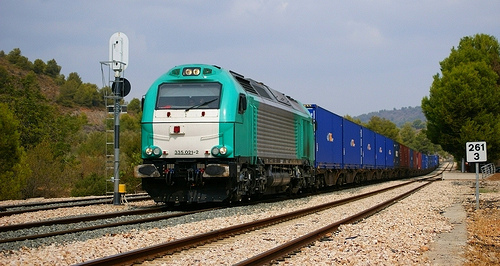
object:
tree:
[420, 33, 499, 173]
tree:
[6, 88, 55, 152]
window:
[249, 80, 276, 102]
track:
[0, 193, 152, 216]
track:
[1, 203, 218, 241]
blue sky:
[265, 20, 383, 89]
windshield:
[157, 81, 223, 109]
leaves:
[43, 117, 68, 142]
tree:
[13, 136, 63, 200]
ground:
[261, 111, 283, 156]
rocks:
[384, 242, 404, 254]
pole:
[475, 162, 480, 210]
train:
[131, 62, 439, 208]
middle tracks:
[0, 200, 247, 245]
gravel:
[0, 179, 457, 263]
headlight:
[153, 148, 161, 155]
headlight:
[219, 147, 227, 155]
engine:
[133, 63, 315, 210]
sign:
[465, 141, 487, 163]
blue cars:
[312, 104, 342, 170]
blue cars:
[343, 119, 362, 169]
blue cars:
[362, 126, 377, 168]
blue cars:
[375, 132, 386, 169]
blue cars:
[385, 136, 394, 168]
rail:
[71, 160, 455, 266]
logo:
[326, 132, 335, 143]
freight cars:
[309, 104, 439, 171]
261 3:
[468, 143, 484, 160]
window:
[154, 79, 222, 110]